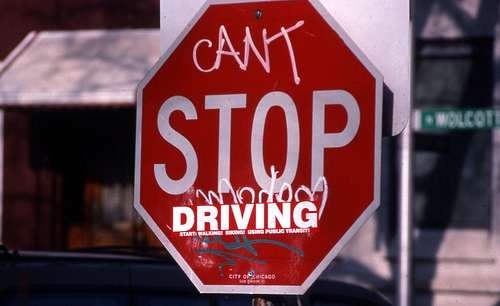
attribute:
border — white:
[199, 281, 310, 294]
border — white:
[301, 57, 384, 284]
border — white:
[131, 10, 201, 285]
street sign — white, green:
[417, 108, 485, 140]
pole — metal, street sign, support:
[393, 136, 413, 302]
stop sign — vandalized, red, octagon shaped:
[127, 3, 384, 293]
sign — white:
[156, 8, 416, 138]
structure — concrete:
[412, 224, 484, 303]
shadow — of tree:
[421, 27, 484, 224]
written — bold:
[151, 76, 361, 196]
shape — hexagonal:
[128, 4, 386, 292]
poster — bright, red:
[128, 2, 387, 291]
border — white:
[196, 279, 302, 298]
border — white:
[300, 3, 383, 290]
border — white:
[132, 4, 203, 298]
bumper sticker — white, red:
[169, 198, 326, 245]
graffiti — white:
[189, 10, 312, 84]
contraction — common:
[188, 20, 308, 82]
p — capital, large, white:
[309, 87, 359, 199]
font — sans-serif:
[152, 89, 364, 201]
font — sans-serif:
[151, 86, 363, 192]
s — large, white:
[146, 92, 206, 202]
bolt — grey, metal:
[252, 10, 262, 20]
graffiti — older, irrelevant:
[203, 169, 335, 213]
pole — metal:
[254, 295, 272, 304]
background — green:
[419, 109, 498, 127]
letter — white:
[474, 112, 486, 126]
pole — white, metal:
[396, 20, 412, 303]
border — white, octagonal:
[134, 0, 384, 297]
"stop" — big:
[153, 90, 361, 193]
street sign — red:
[135, 0, 382, 292]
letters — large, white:
[154, 95, 362, 194]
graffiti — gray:
[192, 231, 305, 271]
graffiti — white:
[188, 16, 306, 83]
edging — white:
[360, 65, 387, 214]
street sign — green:
[410, 106, 485, 134]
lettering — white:
[425, 110, 485, 131]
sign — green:
[410, 107, 484, 128]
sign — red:
[130, 0, 390, 294]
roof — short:
[2, 18, 160, 115]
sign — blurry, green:
[407, 106, 498, 131]